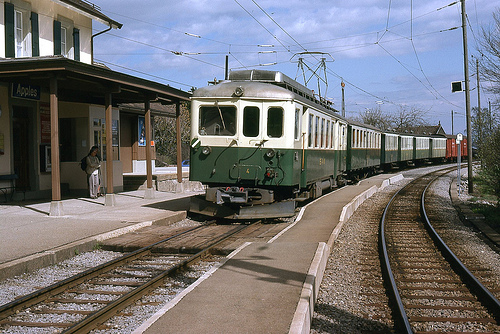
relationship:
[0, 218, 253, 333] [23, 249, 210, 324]
tracks on gravel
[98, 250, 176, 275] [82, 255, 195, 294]
tracks on gravel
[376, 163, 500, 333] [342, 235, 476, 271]
train tracks on gravel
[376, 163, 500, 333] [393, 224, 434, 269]
train tracks on gravel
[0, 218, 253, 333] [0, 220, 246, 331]
tracks on gravel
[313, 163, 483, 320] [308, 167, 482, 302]
train tracks on gravel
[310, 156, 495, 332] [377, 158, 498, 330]
gravel on train tracks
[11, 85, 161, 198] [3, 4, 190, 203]
wall on side of building